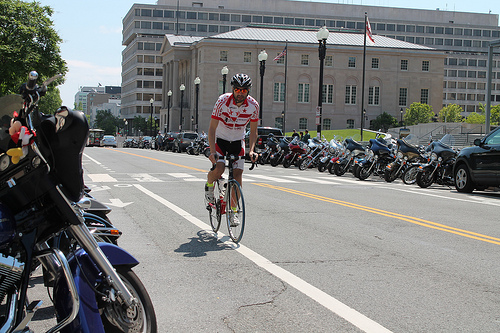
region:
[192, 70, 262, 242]
A man riding a bike.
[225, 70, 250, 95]
A man wearing a bike helmet.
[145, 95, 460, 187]
Motorcycles parked along the roadside.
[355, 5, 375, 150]
A flag on a pole.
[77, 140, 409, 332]
A white line in the road.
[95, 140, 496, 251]
A double yellow line in the road.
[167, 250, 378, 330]
A crack in the pavement.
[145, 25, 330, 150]
Light posts along the road.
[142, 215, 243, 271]
The man's shadow on the road.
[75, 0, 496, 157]
Buildings along the road.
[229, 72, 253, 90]
a black and white bicycle helmet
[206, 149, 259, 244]
a multi speed street bicycle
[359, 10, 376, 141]
a flag and pole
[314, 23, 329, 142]
a street lamp and pole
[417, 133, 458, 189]
a motorcycle parked at the curb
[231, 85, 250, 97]
amber colored riding glasses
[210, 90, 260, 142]
a white and red bicycle riding jersey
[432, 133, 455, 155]
motorcyle windshield and fairing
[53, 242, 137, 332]
a motorcycles blue front fender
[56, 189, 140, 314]
the motorcycles front fork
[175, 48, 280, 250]
a man riding a bicycle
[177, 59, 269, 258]
a man with a red and white jersey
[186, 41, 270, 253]
a man wearing sunglasses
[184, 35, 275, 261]
a man wearing a helmet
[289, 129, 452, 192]
motorcycles parked in a line on the street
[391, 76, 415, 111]
a window in a building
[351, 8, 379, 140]
a flag on a post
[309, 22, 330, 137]
a lamp post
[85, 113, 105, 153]
a bus on the street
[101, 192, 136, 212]
a white directional arrow on the street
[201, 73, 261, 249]
a bicyclist in street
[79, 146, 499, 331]
a paved city street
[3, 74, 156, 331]
a street parked motorcycle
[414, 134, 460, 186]
a street parked motorcycle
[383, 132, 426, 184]
a street parked motorcycle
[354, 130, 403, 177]
a street parked motorcycle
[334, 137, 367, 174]
a street parked motorcycle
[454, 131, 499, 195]
a parked black car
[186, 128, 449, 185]
a row of parked motorcycles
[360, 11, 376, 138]
an American flag on pole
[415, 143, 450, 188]
motorcycle on side of road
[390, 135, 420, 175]
motorcycle on side of road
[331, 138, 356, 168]
motorcycle on side of road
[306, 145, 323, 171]
motorcycle on side of road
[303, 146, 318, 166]
motorcycle on side of road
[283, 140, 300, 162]
motorcycle on side of road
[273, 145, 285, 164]
motorcycle on side of road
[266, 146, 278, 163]
motorcycle on side of road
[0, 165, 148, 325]
motorcycle on side of road